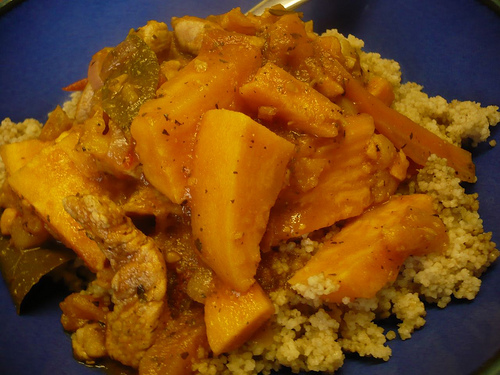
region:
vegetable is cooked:
[192, 110, 292, 288]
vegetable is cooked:
[294, 188, 439, 307]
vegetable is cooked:
[204, 272, 271, 354]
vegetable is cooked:
[8, 143, 146, 281]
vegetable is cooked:
[137, 31, 264, 205]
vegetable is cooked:
[239, 61, 344, 140]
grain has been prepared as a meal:
[0, 14, 499, 365]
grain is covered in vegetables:
[0, 11, 496, 374]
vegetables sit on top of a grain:
[5, 19, 449, 351]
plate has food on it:
[1, 1, 499, 374]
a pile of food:
[7, 4, 499, 371]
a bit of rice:
[383, 324, 400, 341]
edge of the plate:
[459, 350, 499, 374]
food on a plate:
[1, 2, 493, 373]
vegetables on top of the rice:
[1, 3, 499, 373]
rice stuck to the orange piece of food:
[279, 271, 346, 301]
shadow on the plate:
[26, 285, 53, 312]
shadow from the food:
[24, 283, 63, 312]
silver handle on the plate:
[241, 0, 296, 22]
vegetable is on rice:
[135, 35, 266, 203]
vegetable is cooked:
[135, 36, 260, 201]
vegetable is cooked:
[5, 141, 136, 261]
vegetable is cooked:
[197, 270, 267, 350]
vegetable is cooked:
[287, 185, 432, 311]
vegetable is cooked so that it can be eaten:
[260, 110, 375, 245]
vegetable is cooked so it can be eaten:
[240, 55, 340, 130]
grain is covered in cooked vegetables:
[2, 8, 497, 373]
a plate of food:
[32, 37, 442, 372]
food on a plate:
[91, 52, 493, 369]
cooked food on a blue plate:
[72, 55, 491, 343]